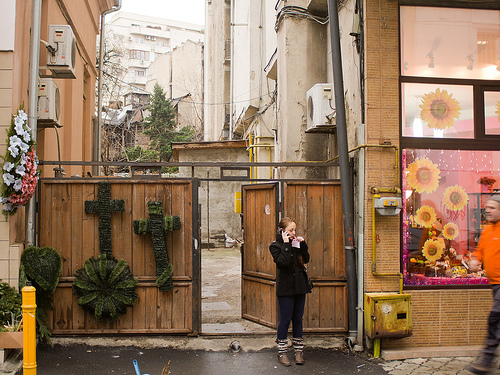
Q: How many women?
A: One.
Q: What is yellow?
A: Flower.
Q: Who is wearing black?
A: The woman.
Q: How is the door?
A: Open.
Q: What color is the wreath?
A: Green.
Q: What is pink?
A: Window sill.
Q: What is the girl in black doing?
A: Talking on phone.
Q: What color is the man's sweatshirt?
A: Orange.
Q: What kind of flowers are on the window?
A: Sunflowers.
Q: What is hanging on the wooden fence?
A: Cross.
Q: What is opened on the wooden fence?
A: Gate.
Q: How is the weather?
A: Rainy and wet.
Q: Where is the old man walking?
A: Sidewalk.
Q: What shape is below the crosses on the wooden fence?
A: Circle.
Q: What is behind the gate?
A: Alley.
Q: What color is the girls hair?
A: Red.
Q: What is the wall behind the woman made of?
A: Wood.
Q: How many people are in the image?
A: 2.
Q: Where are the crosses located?
A: On the fence.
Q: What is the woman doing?
A: Talking on the phone.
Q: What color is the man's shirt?
A: Orange.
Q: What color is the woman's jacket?
A: Black.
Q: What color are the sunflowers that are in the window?
A: Yellow.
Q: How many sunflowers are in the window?
A: 6.